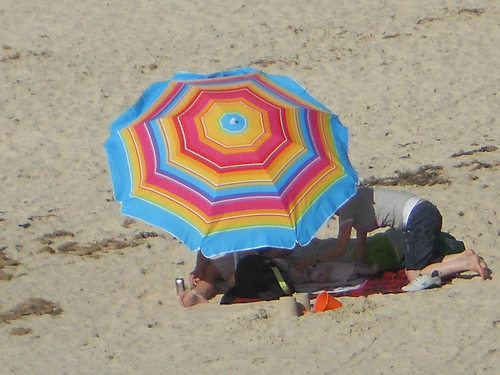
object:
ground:
[1, 1, 498, 375]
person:
[293, 186, 491, 281]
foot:
[467, 254, 487, 280]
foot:
[463, 248, 488, 269]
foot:
[180, 292, 208, 308]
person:
[176, 247, 294, 308]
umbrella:
[105, 66, 358, 259]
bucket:
[314, 290, 341, 311]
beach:
[4, 2, 500, 371]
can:
[175, 278, 183, 295]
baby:
[260, 253, 384, 283]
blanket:
[220, 265, 413, 305]